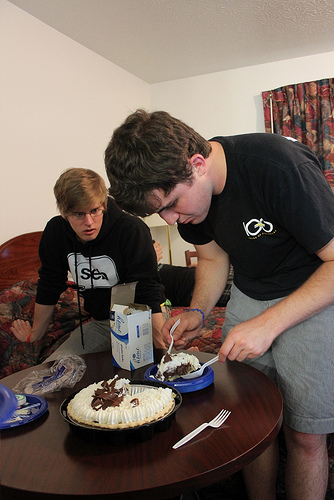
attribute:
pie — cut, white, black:
[51, 376, 186, 445]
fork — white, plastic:
[168, 402, 233, 456]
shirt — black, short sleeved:
[218, 138, 330, 306]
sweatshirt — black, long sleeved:
[16, 223, 164, 325]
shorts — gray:
[229, 298, 332, 433]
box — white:
[105, 282, 160, 374]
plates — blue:
[154, 351, 220, 395]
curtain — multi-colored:
[265, 77, 333, 124]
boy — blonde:
[41, 159, 129, 314]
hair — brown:
[123, 130, 187, 170]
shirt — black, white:
[33, 195, 166, 319]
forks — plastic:
[159, 310, 231, 390]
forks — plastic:
[150, 394, 238, 453]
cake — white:
[64, 372, 176, 427]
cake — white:
[153, 348, 201, 378]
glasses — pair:
[74, 202, 110, 215]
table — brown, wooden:
[19, 362, 271, 457]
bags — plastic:
[13, 343, 89, 401]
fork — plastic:
[176, 411, 238, 442]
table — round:
[179, 384, 270, 453]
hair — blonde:
[53, 167, 106, 218]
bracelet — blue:
[181, 308, 208, 322]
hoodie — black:
[34, 197, 154, 323]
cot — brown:
[1, 228, 43, 287]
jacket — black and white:
[31, 212, 172, 323]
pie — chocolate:
[59, 374, 182, 443]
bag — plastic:
[7, 340, 90, 407]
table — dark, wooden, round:
[4, 336, 295, 498]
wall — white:
[6, 15, 177, 206]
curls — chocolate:
[93, 380, 136, 412]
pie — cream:
[59, 376, 183, 430]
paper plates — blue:
[151, 345, 228, 394]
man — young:
[84, 100, 324, 424]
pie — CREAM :
[150, 347, 203, 379]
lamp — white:
[135, 201, 178, 263]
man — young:
[134, 138, 329, 401]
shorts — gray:
[213, 295, 321, 422]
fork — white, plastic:
[172, 405, 232, 447]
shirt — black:
[178, 134, 324, 302]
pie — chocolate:
[69, 374, 175, 428]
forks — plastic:
[177, 403, 240, 462]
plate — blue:
[151, 357, 216, 392]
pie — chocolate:
[162, 341, 202, 384]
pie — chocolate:
[64, 363, 181, 432]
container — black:
[63, 388, 190, 442]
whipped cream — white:
[80, 378, 155, 417]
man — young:
[32, 163, 166, 301]